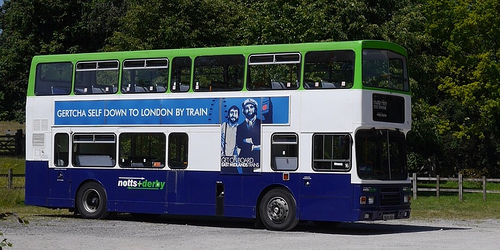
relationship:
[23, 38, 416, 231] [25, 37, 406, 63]
bus has deck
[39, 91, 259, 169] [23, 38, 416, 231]
advertisement on bus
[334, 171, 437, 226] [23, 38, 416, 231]
headlights on bus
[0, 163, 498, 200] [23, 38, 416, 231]
fence behind bus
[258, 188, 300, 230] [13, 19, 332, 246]
black tire of bus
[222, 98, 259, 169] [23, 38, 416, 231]
men on bus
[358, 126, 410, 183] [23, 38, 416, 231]
front window of bus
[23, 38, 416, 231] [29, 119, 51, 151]
bus has vents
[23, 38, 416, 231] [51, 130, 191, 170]
bus has windows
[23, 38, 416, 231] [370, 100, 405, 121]
bus has window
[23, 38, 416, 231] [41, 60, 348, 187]
bus has two floors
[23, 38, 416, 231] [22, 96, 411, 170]
bus has middle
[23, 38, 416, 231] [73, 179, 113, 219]
bus has black tire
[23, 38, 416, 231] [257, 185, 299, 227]
bus has black tire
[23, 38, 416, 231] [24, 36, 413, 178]
bus has windows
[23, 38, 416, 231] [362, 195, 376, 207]
bus has light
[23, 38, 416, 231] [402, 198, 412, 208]
bus has light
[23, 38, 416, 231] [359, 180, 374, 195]
bus has light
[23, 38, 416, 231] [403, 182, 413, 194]
bus has light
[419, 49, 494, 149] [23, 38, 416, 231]
trees behind bus